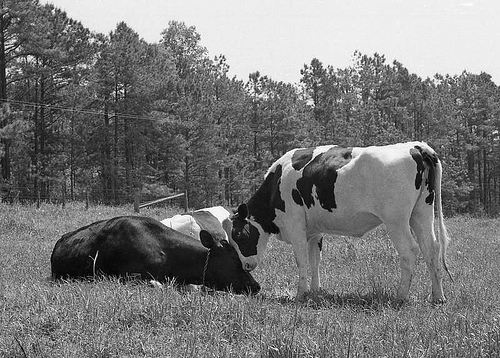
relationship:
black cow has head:
[50, 215, 262, 297] [202, 226, 259, 289]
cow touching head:
[220, 139, 455, 309] [202, 226, 259, 289]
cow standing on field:
[220, 139, 455, 309] [10, 231, 481, 355]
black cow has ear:
[50, 215, 262, 297] [201, 228, 223, 250]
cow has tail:
[220, 139, 455, 309] [426, 148, 452, 281]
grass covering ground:
[1, 190, 498, 356] [2, 200, 497, 352]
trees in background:
[1, 0, 498, 182] [12, 5, 483, 138]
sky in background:
[86, 6, 481, 70] [2, 4, 484, 213]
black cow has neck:
[50, 215, 262, 297] [174, 236, 212, 284]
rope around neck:
[199, 245, 211, 287] [174, 236, 212, 284]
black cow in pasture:
[50, 215, 262, 297] [20, 156, 484, 343]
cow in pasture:
[159, 204, 230, 242] [20, 156, 484, 343]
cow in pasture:
[220, 139, 455, 309] [20, 156, 484, 343]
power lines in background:
[2, 97, 294, 139] [8, 13, 481, 163]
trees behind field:
[1, 0, 500, 219] [9, 195, 482, 346]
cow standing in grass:
[215, 107, 483, 348] [124, 297, 296, 339]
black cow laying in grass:
[50, 215, 262, 297] [1, 190, 498, 356]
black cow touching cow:
[50, 215, 262, 297] [220, 139, 455, 309]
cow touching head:
[220, 139, 455, 309] [226, 203, 269, 270]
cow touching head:
[220, 139, 455, 309] [199, 230, 259, 296]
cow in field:
[220, 139, 455, 309] [0, 199, 497, 356]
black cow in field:
[50, 215, 262, 297] [0, 199, 497, 356]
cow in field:
[156, 204, 233, 246] [0, 199, 497, 356]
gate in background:
[122, 143, 219, 235] [32, 93, 242, 212]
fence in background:
[28, 129, 280, 214] [13, 163, 194, 210]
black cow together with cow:
[50, 215, 262, 297] [218, 130, 464, 317]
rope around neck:
[199, 248, 211, 289] [188, 234, 214, 293]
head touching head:
[223, 200, 270, 274] [196, 228, 260, 295]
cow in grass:
[220, 139, 455, 309] [19, 270, 496, 356]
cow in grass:
[159, 204, 230, 242] [19, 270, 496, 356]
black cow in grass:
[50, 215, 262, 297] [19, 270, 496, 356]